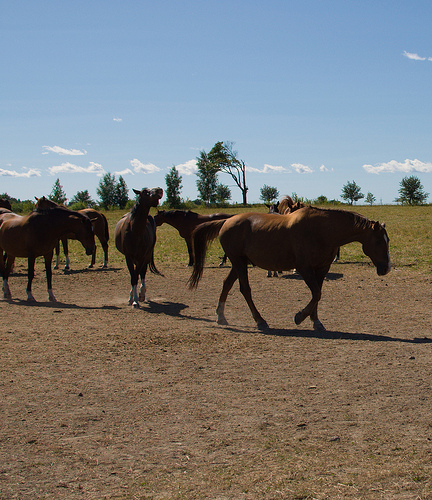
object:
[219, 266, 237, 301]
back legs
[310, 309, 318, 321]
hoove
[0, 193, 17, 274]
horse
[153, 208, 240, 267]
horse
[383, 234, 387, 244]
spot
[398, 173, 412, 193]
leaves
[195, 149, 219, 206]
leafy tree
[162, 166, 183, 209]
leafy tree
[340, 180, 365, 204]
leafy tree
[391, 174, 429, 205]
leafy tree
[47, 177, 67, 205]
leafy tree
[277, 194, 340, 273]
horse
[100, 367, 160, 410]
ground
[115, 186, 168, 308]
horse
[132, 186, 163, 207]
head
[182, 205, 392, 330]
horse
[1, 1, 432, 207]
sky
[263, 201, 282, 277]
horse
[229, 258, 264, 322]
leg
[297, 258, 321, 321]
leg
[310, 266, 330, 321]
leg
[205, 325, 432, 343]
shadow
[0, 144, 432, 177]
cloud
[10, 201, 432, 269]
field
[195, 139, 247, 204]
tree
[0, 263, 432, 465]
field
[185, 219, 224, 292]
tail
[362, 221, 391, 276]
head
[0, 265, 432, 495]
dirt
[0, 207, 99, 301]
horse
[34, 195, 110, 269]
horse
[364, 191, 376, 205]
tree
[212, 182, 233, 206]
tree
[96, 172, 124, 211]
tree